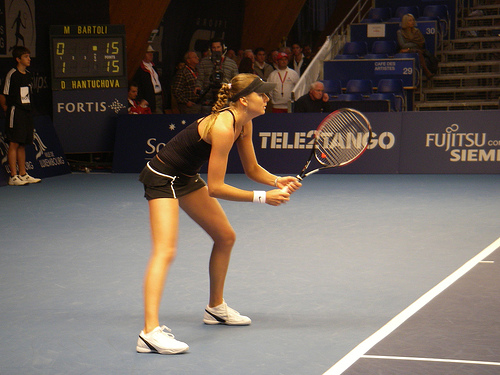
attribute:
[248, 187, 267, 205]
wrist band — white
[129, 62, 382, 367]
player — tennis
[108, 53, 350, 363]
player — tennis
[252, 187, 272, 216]
wrist band — white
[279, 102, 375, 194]
racket — tennis, black, red, white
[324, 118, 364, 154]
netting — white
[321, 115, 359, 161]
logo — black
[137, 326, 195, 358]
shoe — white, athletic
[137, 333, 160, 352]
stripe — black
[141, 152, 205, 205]
shorts — black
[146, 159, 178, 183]
stripe — white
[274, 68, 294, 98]
lanyard — red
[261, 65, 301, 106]
sweater — white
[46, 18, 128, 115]
scoreboard — black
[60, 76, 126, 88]
writing — yellow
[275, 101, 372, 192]
tennis racket — black, red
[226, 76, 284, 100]
visor — black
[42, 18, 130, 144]
scoreboard — electronic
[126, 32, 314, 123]
spectators — standing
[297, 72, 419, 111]
seats — blue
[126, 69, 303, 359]
woman — crouching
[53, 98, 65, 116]
letter — white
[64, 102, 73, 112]
letter — white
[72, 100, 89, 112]
letter — white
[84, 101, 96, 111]
letter — white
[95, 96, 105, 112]
letter — white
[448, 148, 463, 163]
letter — white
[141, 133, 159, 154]
letter — white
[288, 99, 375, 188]
tennis racket — red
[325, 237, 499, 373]
lines — white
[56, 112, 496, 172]
sign — white, blue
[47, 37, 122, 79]
score chart — green, black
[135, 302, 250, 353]
shoes — white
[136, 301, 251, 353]
tennis shoes — white, black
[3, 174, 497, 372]
tennis court — blue, white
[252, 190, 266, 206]
wristband — white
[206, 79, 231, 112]
ponytail — braided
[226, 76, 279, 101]
sunvisor — black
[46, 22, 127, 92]
scoreboard — digital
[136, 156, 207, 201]
shorts — black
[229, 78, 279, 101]
visor — black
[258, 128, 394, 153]
letters — white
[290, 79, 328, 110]
man — old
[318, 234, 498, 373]
line — white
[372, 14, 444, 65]
woman — sitting down